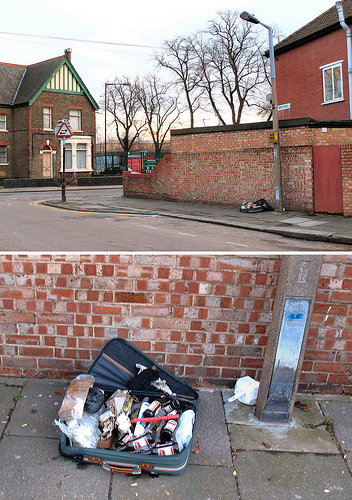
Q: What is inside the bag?
A: Bottles.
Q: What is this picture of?
A: An open bag left on a sidewalk.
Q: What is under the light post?
A: An open bag.